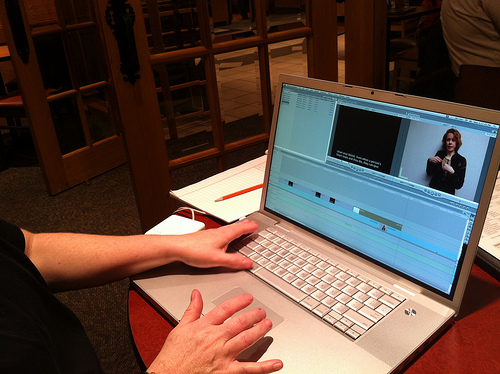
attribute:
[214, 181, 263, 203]
pencil — red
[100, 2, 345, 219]
door — wooden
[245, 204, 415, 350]
keyboard — silver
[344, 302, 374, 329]
button — silver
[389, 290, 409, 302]
button — silver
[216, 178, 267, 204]
pencil — red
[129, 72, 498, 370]
laptop computer — silver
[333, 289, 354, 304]
button — silver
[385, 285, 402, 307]
button — silver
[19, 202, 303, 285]
left hand — man's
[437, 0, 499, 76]
shirt — white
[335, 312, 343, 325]
button — silver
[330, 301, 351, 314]
button — silver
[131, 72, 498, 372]
laptop — silver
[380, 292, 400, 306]
button — silver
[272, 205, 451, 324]
keyboard — silver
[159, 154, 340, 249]
papers — white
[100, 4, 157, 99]
door — wooden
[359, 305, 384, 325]
keyboard — silver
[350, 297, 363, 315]
button — silver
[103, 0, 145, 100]
handle — black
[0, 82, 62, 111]
cushion — red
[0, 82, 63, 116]
chair — stuffed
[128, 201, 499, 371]
table — brown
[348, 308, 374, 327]
button — silver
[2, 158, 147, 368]
floor — carpeted